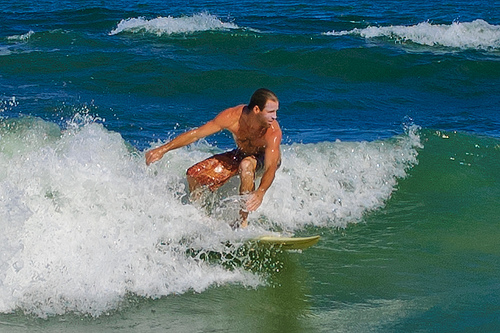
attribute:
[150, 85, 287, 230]
man — surfing, shirtless, wet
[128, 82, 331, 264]
surfing — crouched, topless, standing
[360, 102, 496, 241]
water — blue, green, choppy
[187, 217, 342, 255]
surfboard — white, yellow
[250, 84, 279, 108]
hair — brown, short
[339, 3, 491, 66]
wave — breaking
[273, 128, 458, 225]
wave — white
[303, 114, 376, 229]
water — white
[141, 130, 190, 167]
hand — extended